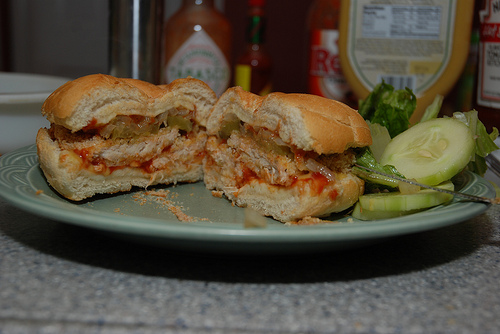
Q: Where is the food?
A: On plate.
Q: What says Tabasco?
A: Hotsauce bottle.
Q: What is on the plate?
A: Sandwich and salad.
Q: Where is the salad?
A: Right side.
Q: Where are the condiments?
A: Behind the plate.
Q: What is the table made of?
A: Glass.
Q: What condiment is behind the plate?
A: Ketchup.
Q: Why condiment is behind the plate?
A: Mustard.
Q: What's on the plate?
A: Food.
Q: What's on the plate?
A: Hamburger.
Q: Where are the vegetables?
A: On the plate.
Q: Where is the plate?
A: On the counter.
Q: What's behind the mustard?
A: Hot sauce.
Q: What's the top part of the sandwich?
A: Bread.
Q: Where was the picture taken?
A: Kitchen.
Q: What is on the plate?
A: Food.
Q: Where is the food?
A: On the plate.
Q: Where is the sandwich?
A: On the plate.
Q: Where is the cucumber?
A: On top of the lettuce.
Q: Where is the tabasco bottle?
A: Behind the plate.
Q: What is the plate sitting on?
A: A table.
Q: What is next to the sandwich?
A: A salad.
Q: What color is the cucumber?
A: Green.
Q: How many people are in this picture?
A: Zero.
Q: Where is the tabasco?
A: In the back.